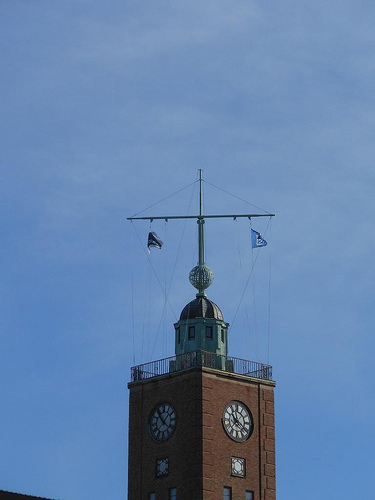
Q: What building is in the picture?
A: Tower clock.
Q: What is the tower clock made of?
A: Bricks.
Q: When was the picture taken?
A: During the daytime.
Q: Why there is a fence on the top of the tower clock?
A: For safety of visitors.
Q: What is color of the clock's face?
A: White.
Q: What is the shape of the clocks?
A: Round.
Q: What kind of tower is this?
A: Clock.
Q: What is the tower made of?
A: Brick.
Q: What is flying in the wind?
A: Flags.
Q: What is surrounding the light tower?
A: Fence.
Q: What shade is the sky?
A: Blue.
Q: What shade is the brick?
A: Red.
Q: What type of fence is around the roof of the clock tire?
A: Metal fence.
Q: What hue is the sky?
A: Blue.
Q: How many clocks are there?
A: Two.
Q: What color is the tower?
A: Red.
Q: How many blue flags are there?
A: One.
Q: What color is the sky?
A: Blue.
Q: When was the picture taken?
A: Daytime.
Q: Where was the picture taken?
A: The dock.